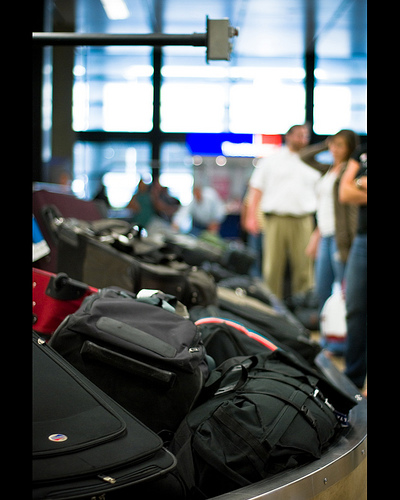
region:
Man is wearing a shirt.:
[251, 146, 318, 225]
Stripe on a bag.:
[195, 312, 287, 363]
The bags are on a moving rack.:
[67, 198, 398, 498]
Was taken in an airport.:
[31, 54, 388, 497]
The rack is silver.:
[272, 442, 381, 497]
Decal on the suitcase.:
[35, 425, 88, 457]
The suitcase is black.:
[35, 340, 171, 499]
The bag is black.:
[163, 347, 343, 452]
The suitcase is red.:
[19, 264, 97, 341]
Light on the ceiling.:
[78, 0, 141, 28]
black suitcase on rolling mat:
[24, 326, 184, 498]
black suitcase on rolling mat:
[50, 279, 215, 411]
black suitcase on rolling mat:
[176, 340, 352, 486]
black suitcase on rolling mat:
[52, 215, 205, 308]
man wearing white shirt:
[235, 113, 323, 298]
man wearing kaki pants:
[247, 123, 321, 303]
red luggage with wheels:
[33, 266, 105, 339]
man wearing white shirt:
[179, 174, 229, 235]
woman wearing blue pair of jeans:
[296, 130, 357, 308]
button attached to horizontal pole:
[29, 15, 242, 68]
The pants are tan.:
[258, 218, 321, 290]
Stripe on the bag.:
[195, 310, 304, 363]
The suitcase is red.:
[34, 259, 84, 324]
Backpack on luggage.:
[72, 276, 213, 401]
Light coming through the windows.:
[159, 1, 307, 130]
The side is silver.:
[279, 442, 376, 498]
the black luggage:
[234, 393, 285, 433]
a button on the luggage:
[46, 423, 72, 443]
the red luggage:
[38, 274, 56, 306]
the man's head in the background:
[285, 129, 318, 149]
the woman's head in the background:
[335, 127, 356, 156]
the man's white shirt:
[270, 165, 314, 208]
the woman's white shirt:
[317, 179, 337, 211]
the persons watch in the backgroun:
[352, 164, 376, 198]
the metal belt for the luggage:
[308, 466, 341, 483]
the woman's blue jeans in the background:
[316, 254, 331, 267]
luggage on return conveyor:
[50, 233, 272, 474]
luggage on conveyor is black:
[56, 296, 325, 475]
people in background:
[258, 120, 372, 293]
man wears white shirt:
[241, 141, 307, 205]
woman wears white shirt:
[306, 165, 351, 241]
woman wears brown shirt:
[322, 161, 356, 219]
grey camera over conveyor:
[189, 17, 230, 73]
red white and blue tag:
[203, 318, 273, 361]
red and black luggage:
[38, 268, 87, 343]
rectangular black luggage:
[77, 267, 237, 463]